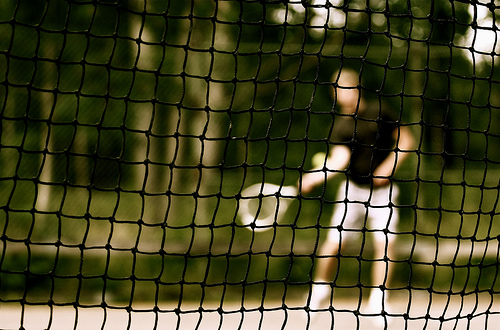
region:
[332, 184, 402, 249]
The white shorts the player is wearing.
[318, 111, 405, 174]
The black shirt the player is wearing.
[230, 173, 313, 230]
The tennis racket in the player's hand.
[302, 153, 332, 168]
The tennis ball in the air.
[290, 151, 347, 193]
The player's left arm.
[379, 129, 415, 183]
The player's right arm.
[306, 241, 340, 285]
The player's left leg.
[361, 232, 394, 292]
The player's right leg.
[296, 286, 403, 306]
The sneakers the player is wearing.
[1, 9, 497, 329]
The black chain linked fence.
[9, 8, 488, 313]
tennis player and trees seen through a net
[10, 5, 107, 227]
tree behind a tennis court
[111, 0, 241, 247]
group of three trees beyond a net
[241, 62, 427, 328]
man with a tennis racket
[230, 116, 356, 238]
right arm ready to return a tennis ball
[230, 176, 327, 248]
tennis racket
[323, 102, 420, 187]
tennis player's brown polo shirt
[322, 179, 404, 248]
tennis player's white shorts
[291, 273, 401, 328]
tennis player's white shoes and socks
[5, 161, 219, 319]
tennis net in front of trees and grass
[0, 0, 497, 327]
net with black nylon cords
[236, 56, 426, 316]
blurry view of tennis player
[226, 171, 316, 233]
man using forehand to hit tennis ball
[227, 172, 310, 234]
tennis racket with white borders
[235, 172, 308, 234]
tennis racket in right hand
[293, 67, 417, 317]
man in black shirt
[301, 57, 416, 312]
man in white shorts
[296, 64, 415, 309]
man in white sneakers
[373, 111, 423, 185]
man's left elbow bent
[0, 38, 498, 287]
chain-link fence behind man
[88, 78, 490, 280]
Net is black color.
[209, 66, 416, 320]
Man is standing behind the net.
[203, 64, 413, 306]
Man is playing tennis.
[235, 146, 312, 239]
Man is holding tennis racket.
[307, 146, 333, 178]
Ball is in air.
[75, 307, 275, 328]
Ground is brown color.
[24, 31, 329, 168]
Trees are behind the man.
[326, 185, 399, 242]
Man is wearing white shorts.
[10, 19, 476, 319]
Day time picture.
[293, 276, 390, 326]
Man is wearing white shoes.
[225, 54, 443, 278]
man playing a sport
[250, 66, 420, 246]
blurry background of photo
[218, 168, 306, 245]
racket in man's hand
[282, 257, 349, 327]
shoe on the person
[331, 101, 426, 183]
shirt on the man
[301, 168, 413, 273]
shorts on the man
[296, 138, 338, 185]
ball in the air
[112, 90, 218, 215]
net in the foreground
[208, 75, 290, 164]
green trees in the background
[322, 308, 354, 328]
brown ground under the man